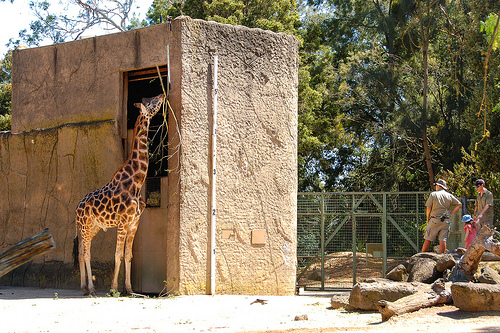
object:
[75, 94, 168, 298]
giraffe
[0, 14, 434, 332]
habitat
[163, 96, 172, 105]
food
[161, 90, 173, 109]
dispenser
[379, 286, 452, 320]
log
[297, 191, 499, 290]
fence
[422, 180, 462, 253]
zoo keeper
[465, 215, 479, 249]
daughter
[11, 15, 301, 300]
buiding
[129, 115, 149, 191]
neck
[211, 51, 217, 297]
pole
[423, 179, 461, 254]
man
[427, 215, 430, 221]
hand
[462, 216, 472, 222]
hat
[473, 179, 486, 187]
visor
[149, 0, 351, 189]
tree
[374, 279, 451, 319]
wood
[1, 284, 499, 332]
ground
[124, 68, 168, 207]
window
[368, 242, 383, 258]
sign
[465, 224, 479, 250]
shirt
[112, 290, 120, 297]
hooves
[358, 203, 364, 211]
hole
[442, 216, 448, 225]
gun